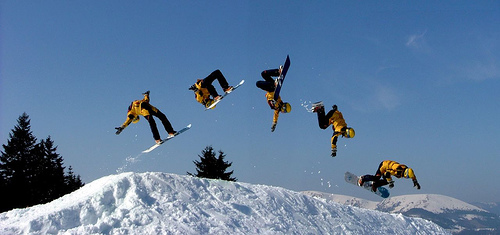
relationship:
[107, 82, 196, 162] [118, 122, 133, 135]
he has arm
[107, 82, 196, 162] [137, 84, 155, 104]
he has arm